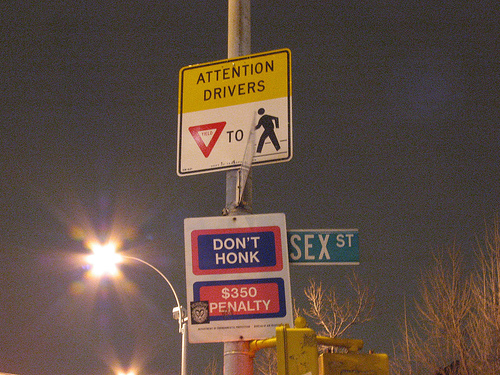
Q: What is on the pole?
A: Signs.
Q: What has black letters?
A: Yellow sign.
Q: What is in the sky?
A: Branches.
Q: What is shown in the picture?
A: Dollar amount of the penalty.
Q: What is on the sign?
A: A person.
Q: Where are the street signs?
A: Metal pole.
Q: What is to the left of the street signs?
A: Street lamp.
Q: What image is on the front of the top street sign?
A: Human figure.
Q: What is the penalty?
A: $350.00.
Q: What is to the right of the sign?
A: Bare tree branches.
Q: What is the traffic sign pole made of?
A: Metal.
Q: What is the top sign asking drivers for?
A: Attention.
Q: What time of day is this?
A: Evening hours.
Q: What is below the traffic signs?
A: Yellow metal traffic box.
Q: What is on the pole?
A: Signs.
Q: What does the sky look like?
A: Dark.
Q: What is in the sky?
A: Street light.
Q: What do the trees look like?
A: No leaves.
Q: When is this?
A: Evening.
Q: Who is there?
A: No one.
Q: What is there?
A: Several signs.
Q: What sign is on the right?
A: Sex st.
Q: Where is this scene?
A: Street.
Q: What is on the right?
A: Trees.